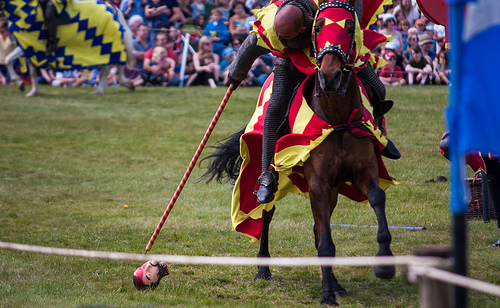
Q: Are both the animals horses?
A: Yes, all the animals are horses.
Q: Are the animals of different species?
A: No, all the animals are horses.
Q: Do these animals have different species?
A: No, all the animals are horses.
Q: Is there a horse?
A: Yes, there is a horse.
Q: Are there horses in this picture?
A: Yes, there is a horse.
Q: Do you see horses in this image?
A: Yes, there is a horse.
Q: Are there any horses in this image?
A: Yes, there is a horse.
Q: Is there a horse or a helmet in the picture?
A: Yes, there is a horse.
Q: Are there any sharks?
A: No, there are no sharks.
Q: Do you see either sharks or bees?
A: No, there are no sharks or bees.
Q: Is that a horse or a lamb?
A: That is a horse.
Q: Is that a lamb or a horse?
A: That is a horse.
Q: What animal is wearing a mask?
A: The horse is wearing a mask.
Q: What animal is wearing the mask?
A: The horse is wearing a mask.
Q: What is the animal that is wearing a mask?
A: The animal is a horse.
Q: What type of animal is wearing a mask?
A: The animal is a horse.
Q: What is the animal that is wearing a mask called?
A: The animal is a horse.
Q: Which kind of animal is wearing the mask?
A: The animal is a horse.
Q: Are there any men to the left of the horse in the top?
A: No, the man is to the right of the horse.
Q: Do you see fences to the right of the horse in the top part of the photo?
A: No, there is a man to the right of the horse.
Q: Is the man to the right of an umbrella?
A: No, the man is to the right of the horse.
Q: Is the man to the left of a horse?
A: No, the man is to the right of a horse.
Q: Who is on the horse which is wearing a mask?
A: The man is on the horse.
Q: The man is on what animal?
A: The man is on the horse.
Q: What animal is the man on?
A: The man is on the horse.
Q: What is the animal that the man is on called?
A: The animal is a horse.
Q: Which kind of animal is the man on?
A: The man is on the horse.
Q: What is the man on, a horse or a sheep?
A: The man is on a horse.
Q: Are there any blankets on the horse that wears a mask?
A: No, there is a man on the horse.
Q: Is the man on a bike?
A: No, the man is on the horse.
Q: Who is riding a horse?
A: The man is riding a horse.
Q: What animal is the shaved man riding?
A: The man is riding a horse.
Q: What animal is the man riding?
A: The man is riding a horse.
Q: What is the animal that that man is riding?
A: The animal is a horse.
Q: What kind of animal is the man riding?
A: The man is riding a horse.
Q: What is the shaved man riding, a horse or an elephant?
A: The man is riding a horse.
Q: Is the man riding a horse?
A: Yes, the man is riding a horse.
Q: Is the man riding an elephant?
A: No, the man is riding a horse.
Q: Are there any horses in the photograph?
A: Yes, there is a horse.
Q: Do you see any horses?
A: Yes, there is a horse.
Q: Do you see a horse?
A: Yes, there is a horse.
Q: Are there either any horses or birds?
A: Yes, there is a horse.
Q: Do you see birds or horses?
A: Yes, there is a horse.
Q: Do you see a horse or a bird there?
A: Yes, there is a horse.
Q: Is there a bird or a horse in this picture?
A: Yes, there is a horse.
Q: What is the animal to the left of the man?
A: The animal is a horse.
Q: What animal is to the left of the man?
A: The animal is a horse.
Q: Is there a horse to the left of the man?
A: Yes, there is a horse to the left of the man.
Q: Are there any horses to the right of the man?
A: No, the horse is to the left of the man.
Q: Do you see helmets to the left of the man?
A: No, there is a horse to the left of the man.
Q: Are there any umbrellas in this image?
A: No, there are no umbrellas.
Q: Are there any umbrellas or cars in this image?
A: No, there are no umbrellas or cars.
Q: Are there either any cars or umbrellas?
A: No, there are no umbrellas or cars.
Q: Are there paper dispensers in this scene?
A: No, there are no paper dispensers.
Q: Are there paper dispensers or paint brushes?
A: No, there are no paper dispensers or paint brushes.